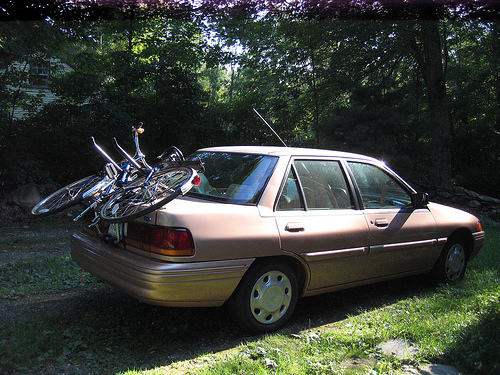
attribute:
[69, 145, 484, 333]
car — old, shiny, tan, sunny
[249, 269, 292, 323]
rim — silver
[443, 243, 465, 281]
rim — silver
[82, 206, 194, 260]
tail lights — wide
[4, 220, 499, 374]
grass — green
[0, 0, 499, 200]
trees — green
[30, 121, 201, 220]
bicycle — blue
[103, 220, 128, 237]
license plate — white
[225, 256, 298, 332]
tire — color black, black, black color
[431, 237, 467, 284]
tire — black, color black, black color